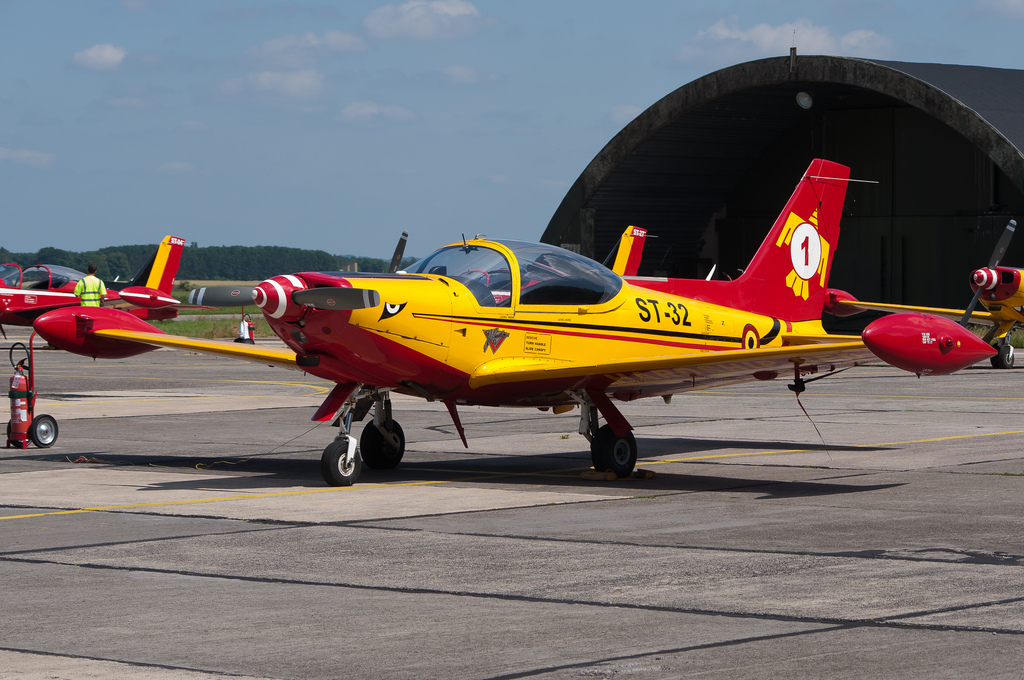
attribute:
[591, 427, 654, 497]
tire — black 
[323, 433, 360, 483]
tire — black 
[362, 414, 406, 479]
tire — black 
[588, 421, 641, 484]
tire — black 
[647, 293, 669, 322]
letter — black 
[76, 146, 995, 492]
plane — yellow  , Red 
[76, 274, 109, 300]
jacket — green 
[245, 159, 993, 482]
airplane — yellow, black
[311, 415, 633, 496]
wheel — black 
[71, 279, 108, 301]
safety shirt — bright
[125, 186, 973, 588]
plane — yellow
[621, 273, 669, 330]
letter — black 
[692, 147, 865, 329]
tail — red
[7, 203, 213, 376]
airplane — black , yellow 